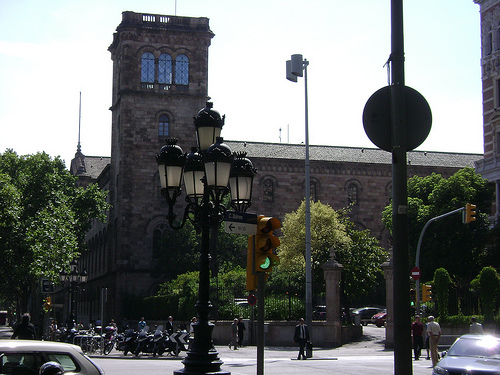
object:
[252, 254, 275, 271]
light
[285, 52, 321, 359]
light pole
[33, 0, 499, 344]
building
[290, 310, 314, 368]
man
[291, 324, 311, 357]
suit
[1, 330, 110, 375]
car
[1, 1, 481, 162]
sky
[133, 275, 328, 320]
fence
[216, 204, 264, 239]
street sign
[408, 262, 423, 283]
road sign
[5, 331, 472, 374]
street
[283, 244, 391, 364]
corner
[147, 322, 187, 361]
motorcycle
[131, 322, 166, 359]
motorcycle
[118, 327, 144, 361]
motorcycle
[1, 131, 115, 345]
tree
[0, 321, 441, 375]
sidewalk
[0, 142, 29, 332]
tree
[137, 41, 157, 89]
window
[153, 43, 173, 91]
window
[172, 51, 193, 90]
window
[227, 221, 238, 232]
arrow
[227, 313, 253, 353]
couple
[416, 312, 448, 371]
man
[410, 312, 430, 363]
man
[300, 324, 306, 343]
tie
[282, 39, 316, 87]
light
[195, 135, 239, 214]
light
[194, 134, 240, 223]
metal case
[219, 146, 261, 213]
light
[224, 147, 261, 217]
metal case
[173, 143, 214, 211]
light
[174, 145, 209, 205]
metal case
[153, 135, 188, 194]
light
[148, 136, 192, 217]
metal case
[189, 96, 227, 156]
light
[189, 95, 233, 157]
metal case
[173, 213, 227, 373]
light post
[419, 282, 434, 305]
stoplight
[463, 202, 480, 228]
stoplight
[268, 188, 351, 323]
tree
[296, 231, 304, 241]
leaves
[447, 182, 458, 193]
leaves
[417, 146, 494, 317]
tree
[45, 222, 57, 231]
leaves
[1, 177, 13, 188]
leaves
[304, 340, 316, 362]
suitcase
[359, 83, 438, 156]
sign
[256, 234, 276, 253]
light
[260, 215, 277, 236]
light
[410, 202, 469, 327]
pole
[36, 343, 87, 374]
back window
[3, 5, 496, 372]
scene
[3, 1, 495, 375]
town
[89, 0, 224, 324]
tower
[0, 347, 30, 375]
passenger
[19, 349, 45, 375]
passenger